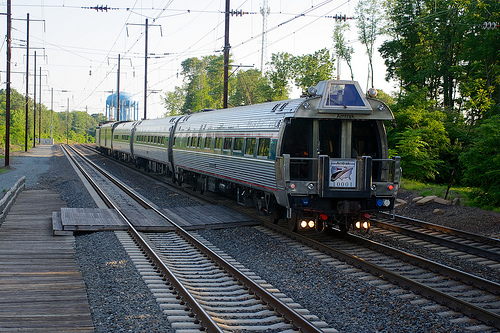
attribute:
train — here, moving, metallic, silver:
[93, 80, 405, 236]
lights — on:
[299, 214, 374, 235]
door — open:
[288, 120, 379, 181]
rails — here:
[284, 154, 403, 168]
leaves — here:
[403, 31, 450, 79]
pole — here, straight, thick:
[215, 0, 238, 112]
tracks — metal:
[371, 223, 492, 314]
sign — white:
[330, 155, 357, 189]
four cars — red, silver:
[96, 120, 287, 203]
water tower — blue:
[99, 92, 144, 120]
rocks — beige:
[80, 233, 129, 330]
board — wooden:
[41, 202, 259, 236]